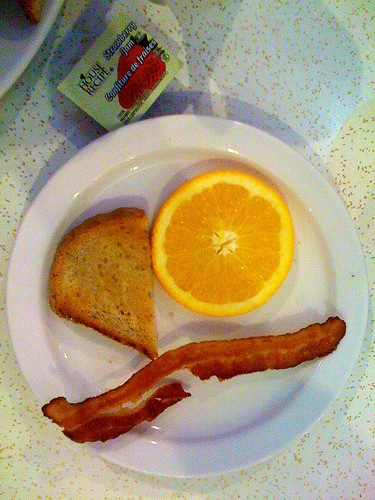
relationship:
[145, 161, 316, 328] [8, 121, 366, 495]
orange on top of plate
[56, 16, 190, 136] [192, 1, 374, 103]
jam on top of table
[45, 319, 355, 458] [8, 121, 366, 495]
bacon on top of plate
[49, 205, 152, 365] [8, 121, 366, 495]
toast on top of plate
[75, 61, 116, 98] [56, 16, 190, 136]
words are on top of jam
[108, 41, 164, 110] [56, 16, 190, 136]
strawberry on top of jam